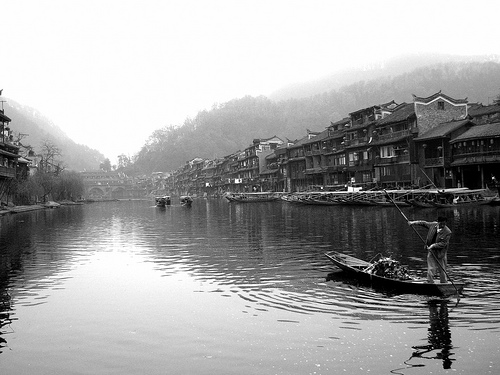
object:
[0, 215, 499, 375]
light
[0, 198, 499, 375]
ripples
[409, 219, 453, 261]
jacket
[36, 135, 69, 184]
tree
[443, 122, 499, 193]
buildings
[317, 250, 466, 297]
boat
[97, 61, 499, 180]
forest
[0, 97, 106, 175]
hill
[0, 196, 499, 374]
river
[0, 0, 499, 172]
sky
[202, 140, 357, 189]
lights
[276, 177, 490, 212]
object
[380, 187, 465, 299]
paddle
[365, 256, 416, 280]
color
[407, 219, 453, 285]
suit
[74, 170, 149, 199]
bridge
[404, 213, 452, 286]
he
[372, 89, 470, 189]
houses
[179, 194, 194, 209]
boats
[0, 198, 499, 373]
waves